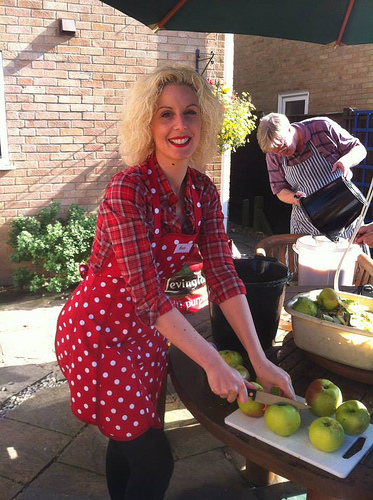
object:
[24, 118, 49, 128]
brick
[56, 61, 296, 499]
woman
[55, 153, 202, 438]
apron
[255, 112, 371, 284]
man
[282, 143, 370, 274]
apron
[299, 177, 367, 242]
bucket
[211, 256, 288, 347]
trash can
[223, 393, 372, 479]
cutting board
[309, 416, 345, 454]
apple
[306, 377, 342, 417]
apple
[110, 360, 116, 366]
polka dot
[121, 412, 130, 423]
polka dot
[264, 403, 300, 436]
apple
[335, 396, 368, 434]
apples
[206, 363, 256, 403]
hand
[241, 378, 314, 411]
knife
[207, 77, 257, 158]
plant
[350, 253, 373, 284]
chair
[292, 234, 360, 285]
bucket